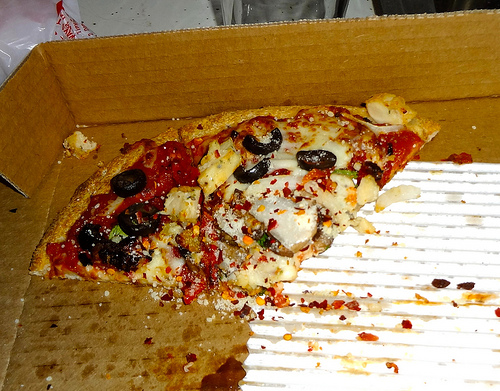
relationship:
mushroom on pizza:
[363, 90, 415, 124] [87, 58, 403, 325]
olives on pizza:
[362, 161, 383, 180] [27, 95, 439, 303]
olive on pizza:
[242, 127, 283, 154] [27, 95, 439, 303]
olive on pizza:
[296, 150, 337, 170] [27, 95, 439, 303]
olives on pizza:
[110, 169, 147, 198] [27, 95, 439, 303]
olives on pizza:
[118, 205, 158, 235] [27, 95, 439, 303]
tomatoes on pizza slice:
[92, 152, 227, 264] [181, 92, 438, 290]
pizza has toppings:
[27, 95, 439, 303] [104, 157, 390, 320]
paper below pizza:
[349, 193, 451, 295] [27, 95, 439, 303]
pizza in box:
[27, 95, 439, 303] [28, 10, 215, 151]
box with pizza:
[0, 9, 499, 391] [27, 95, 439, 303]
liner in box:
[238, 147, 483, 359] [18, 16, 475, 376]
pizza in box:
[27, 95, 439, 303] [18, 16, 475, 376]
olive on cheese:
[302, 149, 336, 168] [203, 122, 356, 251]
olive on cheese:
[237, 161, 269, 174] [203, 122, 356, 251]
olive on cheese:
[248, 132, 285, 148] [203, 122, 356, 251]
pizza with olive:
[27, 95, 439, 303] [239, 123, 282, 153]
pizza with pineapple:
[27, 95, 439, 303] [201, 139, 241, 186]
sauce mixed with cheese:
[383, 134, 421, 170] [331, 131, 372, 212]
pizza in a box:
[27, 95, 439, 303] [0, 9, 499, 391]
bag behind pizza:
[0, 0, 94, 87] [27, 95, 439, 303]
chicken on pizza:
[194, 133, 247, 199] [27, 95, 439, 303]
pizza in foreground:
[27, 95, 439, 303] [3, 91, 498, 389]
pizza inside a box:
[27, 95, 439, 303] [0, 7, 497, 386]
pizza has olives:
[69, 96, 454, 317] [225, 126, 305, 196]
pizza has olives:
[69, 96, 454, 317] [95, 160, 160, 275]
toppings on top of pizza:
[107, 150, 379, 286] [27, 95, 439, 303]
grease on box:
[30, 295, 186, 383] [0, 7, 497, 386]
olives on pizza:
[356, 160, 382, 177] [27, 95, 439, 303]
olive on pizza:
[233, 161, 268, 183] [27, 95, 439, 303]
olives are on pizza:
[110, 169, 147, 198] [110, 96, 430, 308]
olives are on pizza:
[108, 166, 147, 195] [128, 149, 292, 289]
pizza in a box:
[27, 95, 439, 303] [0, 7, 497, 386]